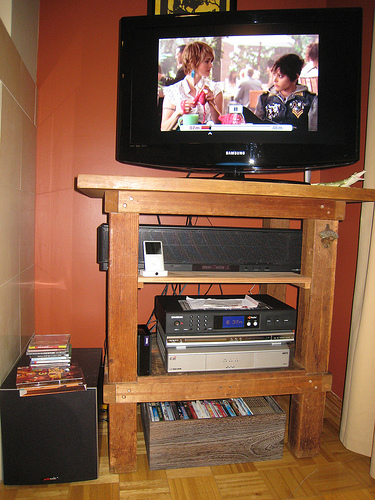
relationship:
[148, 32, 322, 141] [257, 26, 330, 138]
screen has part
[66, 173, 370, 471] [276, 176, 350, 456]
stand has part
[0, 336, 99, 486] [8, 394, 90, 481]
speaker has part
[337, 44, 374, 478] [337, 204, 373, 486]
curtain has part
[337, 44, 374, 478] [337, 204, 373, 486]
curtain has edge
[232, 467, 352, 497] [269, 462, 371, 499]
floor has part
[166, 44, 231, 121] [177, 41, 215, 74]
lady has hair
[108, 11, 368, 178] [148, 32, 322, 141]
television has movie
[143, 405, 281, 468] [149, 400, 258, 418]
box has movies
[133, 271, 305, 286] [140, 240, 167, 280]
shelf has ipod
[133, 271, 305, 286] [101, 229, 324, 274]
shelf has speaker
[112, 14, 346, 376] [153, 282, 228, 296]
electronics have wires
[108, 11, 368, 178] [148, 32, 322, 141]
television has screen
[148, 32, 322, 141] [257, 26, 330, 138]
video has part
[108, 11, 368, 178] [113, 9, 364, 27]
television has edge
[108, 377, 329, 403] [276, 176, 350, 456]
wood has part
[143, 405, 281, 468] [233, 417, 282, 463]
box has part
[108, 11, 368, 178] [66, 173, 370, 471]
television has stand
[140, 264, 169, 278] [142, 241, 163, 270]
charger has phone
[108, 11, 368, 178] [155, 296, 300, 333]
tv has cable box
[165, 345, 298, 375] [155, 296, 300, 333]
dvd player under cable box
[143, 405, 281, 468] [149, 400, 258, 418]
box has cds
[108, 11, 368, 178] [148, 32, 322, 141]
tv has program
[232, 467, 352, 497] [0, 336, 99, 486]
floor has speaker